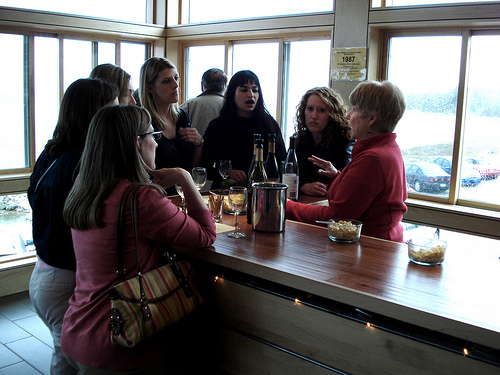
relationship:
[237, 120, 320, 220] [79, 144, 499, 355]
bottles on counter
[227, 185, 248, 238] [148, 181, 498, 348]
glass on counter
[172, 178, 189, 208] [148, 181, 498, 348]
glass on counter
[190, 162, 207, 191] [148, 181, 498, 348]
glass on counter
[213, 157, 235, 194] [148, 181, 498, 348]
glass on counter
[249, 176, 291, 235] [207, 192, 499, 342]
bucket sits on counter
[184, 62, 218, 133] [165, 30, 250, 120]
woman looking out window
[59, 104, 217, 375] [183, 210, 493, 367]
she standing next bar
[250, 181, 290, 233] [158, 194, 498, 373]
bucket on top bar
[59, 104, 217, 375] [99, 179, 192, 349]
she holding purse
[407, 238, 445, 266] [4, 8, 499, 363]
glass bowl on top bar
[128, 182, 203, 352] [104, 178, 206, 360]
straps attached to purse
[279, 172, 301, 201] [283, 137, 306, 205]
label attached to wine bottle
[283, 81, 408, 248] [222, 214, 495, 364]
woman standing at table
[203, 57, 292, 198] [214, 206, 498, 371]
woman standing at table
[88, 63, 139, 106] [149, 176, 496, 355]
woman standing at table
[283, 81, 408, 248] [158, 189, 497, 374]
woman standing at table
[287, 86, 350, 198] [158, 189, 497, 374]
woman standing at table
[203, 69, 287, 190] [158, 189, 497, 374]
woman standing at table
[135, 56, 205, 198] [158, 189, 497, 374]
woman standing at table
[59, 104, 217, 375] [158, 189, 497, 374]
she standing at table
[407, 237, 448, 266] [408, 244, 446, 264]
bowl of food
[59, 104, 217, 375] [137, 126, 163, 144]
she wearing glasses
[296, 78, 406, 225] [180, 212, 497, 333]
woman standing at table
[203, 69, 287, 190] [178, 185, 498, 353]
woman standing at table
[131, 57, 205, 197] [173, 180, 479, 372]
woman standing at table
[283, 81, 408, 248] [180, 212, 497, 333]
woman standing at table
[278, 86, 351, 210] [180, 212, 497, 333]
woman standing at table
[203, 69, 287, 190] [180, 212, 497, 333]
woman standing at table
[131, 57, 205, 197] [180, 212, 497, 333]
woman standing at table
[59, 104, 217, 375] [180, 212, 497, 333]
she standing at table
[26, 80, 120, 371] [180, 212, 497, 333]
woman standing at table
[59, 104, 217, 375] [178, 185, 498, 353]
she standing at table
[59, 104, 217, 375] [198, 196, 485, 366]
she standing at table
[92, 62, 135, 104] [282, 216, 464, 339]
woman standing at table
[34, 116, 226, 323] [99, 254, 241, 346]
she holding onto her purse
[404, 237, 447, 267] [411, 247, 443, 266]
bowl of nuts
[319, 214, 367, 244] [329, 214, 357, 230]
bowl of nuts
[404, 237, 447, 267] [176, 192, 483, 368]
bowl on counter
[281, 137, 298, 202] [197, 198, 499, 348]
bottles on counter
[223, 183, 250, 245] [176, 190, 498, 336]
glass on counter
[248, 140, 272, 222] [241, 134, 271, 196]
bottle on bar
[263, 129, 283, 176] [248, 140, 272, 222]
bottle on bottle